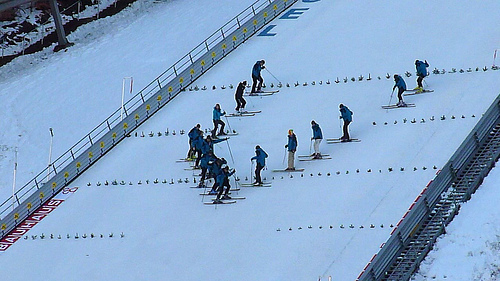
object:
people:
[248, 144, 270, 188]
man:
[233, 81, 251, 114]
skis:
[224, 110, 259, 117]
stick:
[262, 68, 282, 85]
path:
[0, 0, 500, 280]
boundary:
[0, 32, 250, 241]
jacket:
[188, 129, 198, 145]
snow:
[0, 0, 499, 281]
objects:
[83, 179, 95, 190]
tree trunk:
[46, 0, 71, 49]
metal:
[263, 18, 276, 24]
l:
[254, 24, 280, 37]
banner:
[0, 199, 60, 252]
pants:
[215, 183, 230, 198]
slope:
[52, 224, 327, 281]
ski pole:
[243, 165, 258, 185]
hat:
[287, 130, 295, 133]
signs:
[242, 27, 250, 35]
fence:
[0, 32, 255, 244]